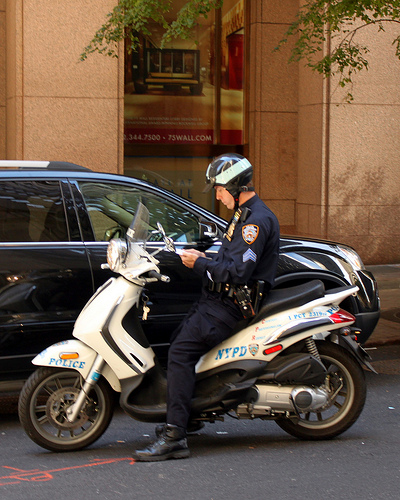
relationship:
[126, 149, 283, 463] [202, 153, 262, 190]
officer wearing helmet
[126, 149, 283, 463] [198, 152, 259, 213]
officer wearing helmet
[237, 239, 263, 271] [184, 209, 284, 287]
stripes on sleeve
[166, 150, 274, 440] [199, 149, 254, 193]
policeman wearing helmet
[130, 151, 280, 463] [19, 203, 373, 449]
police officer on motorcycle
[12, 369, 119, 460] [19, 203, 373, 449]
wheel on motorcycle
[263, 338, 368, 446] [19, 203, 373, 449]
wheel on motorcycle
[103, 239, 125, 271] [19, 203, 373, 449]
headlight on motorcycle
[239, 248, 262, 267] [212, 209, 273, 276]
patch on uniform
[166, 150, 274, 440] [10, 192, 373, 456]
policeman on scooter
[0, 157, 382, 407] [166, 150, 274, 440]
suv from policeman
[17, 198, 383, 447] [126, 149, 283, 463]
bike under officer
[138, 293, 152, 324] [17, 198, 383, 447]
keys hanging from bike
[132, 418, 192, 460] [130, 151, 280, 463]
foot of police officer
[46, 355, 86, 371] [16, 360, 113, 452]
word above front tire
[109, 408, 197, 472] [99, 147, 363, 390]
foot of officer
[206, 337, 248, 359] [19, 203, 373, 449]
letters on motorcycle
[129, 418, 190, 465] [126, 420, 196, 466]
black boot on foot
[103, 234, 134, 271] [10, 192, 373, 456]
headlight on scooter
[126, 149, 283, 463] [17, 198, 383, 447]
officer on bike